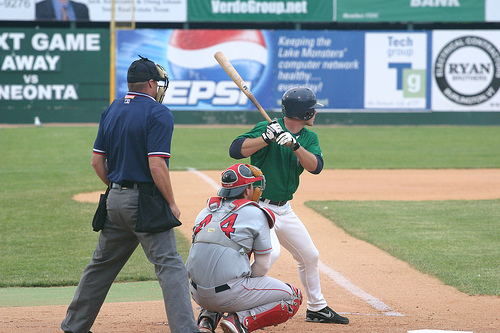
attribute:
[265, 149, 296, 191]
shirt — dark green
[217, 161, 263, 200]
cap — grey, red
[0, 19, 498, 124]
wall — fence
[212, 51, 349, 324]
player — baseball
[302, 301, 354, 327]
sneaker — black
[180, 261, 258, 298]
belt — black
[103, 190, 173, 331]
pants — grey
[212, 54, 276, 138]
bat — baseball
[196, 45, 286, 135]
bat — wooden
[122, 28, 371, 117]
advertisement — Pepsi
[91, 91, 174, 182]
shirt — blue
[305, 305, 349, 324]
cleat — black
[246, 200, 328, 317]
pants — white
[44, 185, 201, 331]
pants — gray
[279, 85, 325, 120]
helmet — black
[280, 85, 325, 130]
head — batters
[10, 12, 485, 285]
game — baseball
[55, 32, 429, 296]
game — baseball